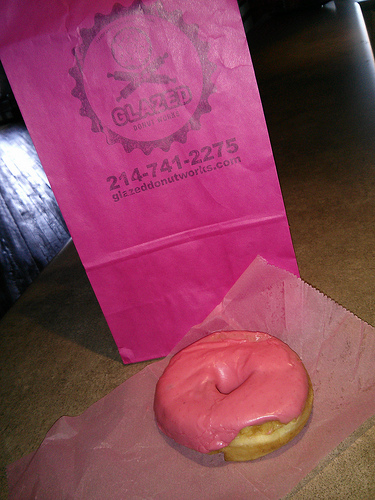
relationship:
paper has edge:
[21, 244, 373, 500] [252, 252, 374, 331]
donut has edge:
[151, 319, 318, 471] [222, 407, 317, 466]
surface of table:
[16, 275, 102, 431] [1, 8, 374, 496]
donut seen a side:
[151, 319, 318, 471] [222, 407, 317, 466]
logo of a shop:
[66, 5, 226, 168] [66, 7, 254, 210]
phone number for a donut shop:
[102, 134, 247, 196] [66, 7, 254, 210]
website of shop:
[97, 150, 246, 208] [66, 7, 254, 210]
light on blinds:
[2, 135, 46, 240] [3, 120, 62, 298]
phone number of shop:
[102, 134, 247, 196] [66, 7, 254, 210]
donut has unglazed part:
[151, 319, 318, 471] [235, 420, 293, 463]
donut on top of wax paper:
[151, 319, 318, 471] [21, 244, 373, 500]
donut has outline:
[151, 319, 318, 471] [140, 385, 313, 475]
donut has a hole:
[151, 319, 318, 471] [206, 357, 260, 400]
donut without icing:
[151, 319, 318, 471] [235, 420, 293, 463]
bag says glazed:
[3, 2, 315, 369] [106, 80, 197, 131]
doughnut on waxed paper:
[151, 319, 318, 471] [21, 244, 373, 500]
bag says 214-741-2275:
[3, 2, 315, 369] [102, 134, 247, 196]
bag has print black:
[3, 2, 315, 369] [66, 7, 254, 210]